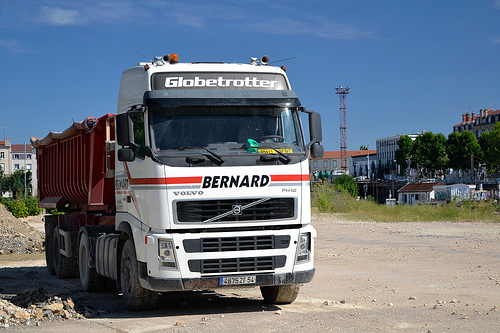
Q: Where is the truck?
A: In the dirt.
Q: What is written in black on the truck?
A: Bernard.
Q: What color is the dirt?
A: Brown.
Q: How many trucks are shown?
A: 1.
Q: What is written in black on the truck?
A: Bernard.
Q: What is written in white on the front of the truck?
A: Globetrotter.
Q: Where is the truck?
A: On dirt.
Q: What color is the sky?
A: Blue.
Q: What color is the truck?
A: White.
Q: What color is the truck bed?
A: Red.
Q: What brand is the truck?
A: Volvo.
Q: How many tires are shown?
A: 5.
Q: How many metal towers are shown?
A: 1.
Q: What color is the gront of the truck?
A: White.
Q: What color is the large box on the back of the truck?
A: Red.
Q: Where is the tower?
A: In the distance, on the right.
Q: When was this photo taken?
A: Daytime.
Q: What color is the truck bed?
A: Red.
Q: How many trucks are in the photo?
A: One.